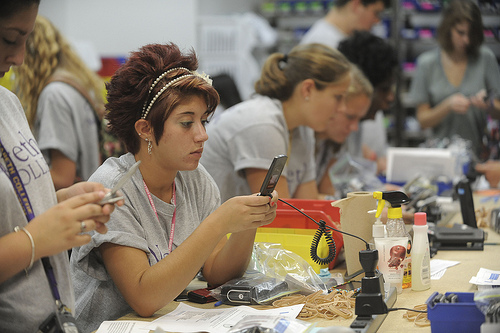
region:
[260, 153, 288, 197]
part of a gray cellphone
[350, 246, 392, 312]
a large black stamp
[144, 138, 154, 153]
a girl's earring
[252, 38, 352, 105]
a woman's brown hair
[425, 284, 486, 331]
a small blue bucket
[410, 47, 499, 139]
a woman's gray shirt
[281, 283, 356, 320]
a pile of rubber bands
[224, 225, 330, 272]
a yellow bucket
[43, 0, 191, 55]
part of a white wall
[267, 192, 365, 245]
a long black cord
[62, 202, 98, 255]
a girl wearing a ring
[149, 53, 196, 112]
a girl wearing a headband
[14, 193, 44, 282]
a girl wearing a bracelet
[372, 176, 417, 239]
a yellow and black spray bottle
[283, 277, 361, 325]
rubber bands on the table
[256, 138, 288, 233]
a girl looking at a phone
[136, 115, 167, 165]
a girl wearing ear rings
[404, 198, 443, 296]
a bottle with a pink lid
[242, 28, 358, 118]
a girl with her hair pulled back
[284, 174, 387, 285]
a phone cord connected to the phone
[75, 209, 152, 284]
sleeves rolled up on grey t-shirt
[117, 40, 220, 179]
woman wearing a pearl headband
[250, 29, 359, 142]
woman with brown hair in a pony tail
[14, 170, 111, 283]
woman wearing a silver bracelet and ring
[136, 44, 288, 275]
woman looking at her cell phone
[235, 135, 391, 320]
black cell phone plugged into charger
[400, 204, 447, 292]
clear bottle with pink cap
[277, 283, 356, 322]
pile of elastic rubber bands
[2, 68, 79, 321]
woman wearing a purple lanyard around her neck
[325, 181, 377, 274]
roll of brown paper towels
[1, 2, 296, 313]
two women on their cell phones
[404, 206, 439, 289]
clear bottle with a pink cap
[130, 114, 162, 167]
woman with three earrings in her ear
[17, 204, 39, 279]
silver bracelet on woman's wrist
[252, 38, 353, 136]
woman with brown hair in pony tail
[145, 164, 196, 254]
pink lanyard around womans neck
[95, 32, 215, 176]
Woman wearing head band.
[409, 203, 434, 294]
Bottle of fingernail polish remover.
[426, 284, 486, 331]
Blue container in the front.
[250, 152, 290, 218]
Cell phone in hand.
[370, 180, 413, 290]
Spray bottle on the table.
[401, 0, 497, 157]
Women wearing gray shirt.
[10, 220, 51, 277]
Silver bracelet on the wrist.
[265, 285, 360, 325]
A pile of rubberbands.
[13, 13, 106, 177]
the woman has blond hair.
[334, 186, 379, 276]
Roll of brown paper towels on table.